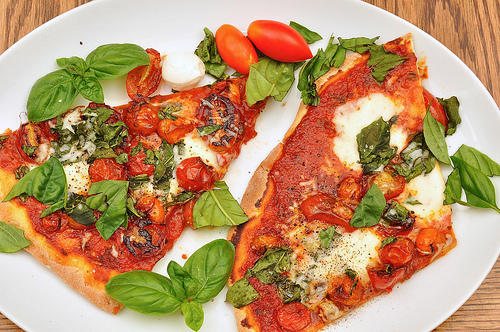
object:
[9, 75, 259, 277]
sauce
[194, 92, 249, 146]
onion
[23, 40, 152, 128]
basil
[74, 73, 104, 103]
leaf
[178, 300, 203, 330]
leaf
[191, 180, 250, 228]
leaf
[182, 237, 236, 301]
leaf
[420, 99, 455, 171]
leaf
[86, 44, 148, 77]
leaf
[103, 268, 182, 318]
leaf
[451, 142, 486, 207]
leaf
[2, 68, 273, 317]
pizza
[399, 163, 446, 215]
cheese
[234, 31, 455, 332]
slice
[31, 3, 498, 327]
table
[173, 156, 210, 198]
tomato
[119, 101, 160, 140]
tomato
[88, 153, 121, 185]
tomato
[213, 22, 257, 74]
red tomatoes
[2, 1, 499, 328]
plate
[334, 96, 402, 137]
white cheese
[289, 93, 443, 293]
cheese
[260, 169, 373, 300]
spices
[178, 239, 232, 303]
leaves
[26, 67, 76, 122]
leaf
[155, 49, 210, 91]
cheese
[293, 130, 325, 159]
sauce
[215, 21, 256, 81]
red tomato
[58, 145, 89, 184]
cheese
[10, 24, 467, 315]
pizza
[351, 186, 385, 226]
basil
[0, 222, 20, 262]
green leaf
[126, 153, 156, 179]
tomatoes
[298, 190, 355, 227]
tomatoes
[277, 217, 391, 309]
cheese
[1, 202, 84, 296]
crust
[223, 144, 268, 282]
crust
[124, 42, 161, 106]
grape tomato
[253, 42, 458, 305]
pizza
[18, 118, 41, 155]
mushroom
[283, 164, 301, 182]
sauce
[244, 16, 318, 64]
tomatoes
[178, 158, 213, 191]
tomatoes